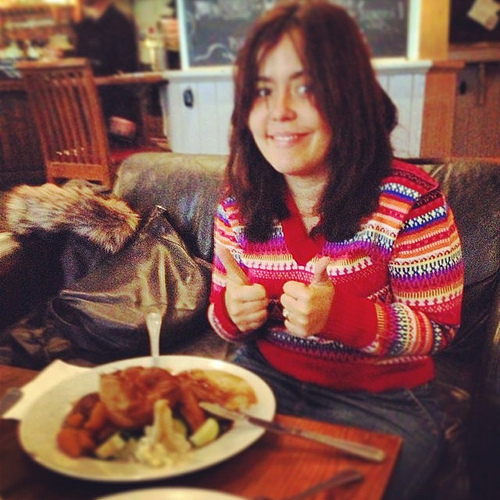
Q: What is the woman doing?
A: Giving two thumbs up.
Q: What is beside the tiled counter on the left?
A: A brown wooden chair.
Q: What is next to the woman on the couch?
A: A purse.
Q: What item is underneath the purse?
A: A black jacket with fur.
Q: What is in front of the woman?
A: A bowl of food.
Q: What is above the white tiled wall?
A: A black chalkboard.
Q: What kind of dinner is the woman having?
A: A chicken dinner.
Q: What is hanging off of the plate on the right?
A: A knife.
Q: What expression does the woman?
A: She is smiling.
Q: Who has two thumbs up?
A: The woman.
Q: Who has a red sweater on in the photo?
A: The woman.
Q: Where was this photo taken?
A: A restaurant.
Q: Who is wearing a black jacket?
A: The chair.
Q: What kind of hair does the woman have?
A: Brown.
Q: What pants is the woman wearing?
A: Jeans.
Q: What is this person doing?
A: Thumbs up.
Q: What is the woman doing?
A: Eating.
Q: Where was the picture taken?
A: Living Room.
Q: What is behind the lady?
A: Kitchen.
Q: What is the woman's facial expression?
A: Smile.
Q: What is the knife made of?
A: Metal.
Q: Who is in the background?
A: Chef.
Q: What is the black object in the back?
A: Chalkboard.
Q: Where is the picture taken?
A: A restaurant.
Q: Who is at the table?
A: A woman.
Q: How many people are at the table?
A: One.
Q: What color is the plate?
A: White.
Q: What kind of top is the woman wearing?
A: Sweater.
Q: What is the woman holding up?
A: Her thumbs.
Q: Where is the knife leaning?
A: On the plate.